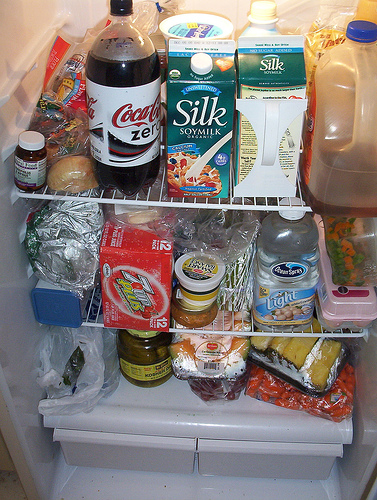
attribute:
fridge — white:
[1, 5, 375, 498]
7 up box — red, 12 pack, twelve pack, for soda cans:
[95, 211, 177, 337]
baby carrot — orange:
[336, 380, 355, 401]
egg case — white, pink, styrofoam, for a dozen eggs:
[311, 213, 375, 337]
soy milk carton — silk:
[161, 33, 238, 208]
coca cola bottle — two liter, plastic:
[82, 2, 166, 199]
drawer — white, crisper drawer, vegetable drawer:
[48, 427, 199, 483]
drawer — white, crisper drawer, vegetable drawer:
[195, 432, 348, 485]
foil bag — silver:
[20, 201, 107, 298]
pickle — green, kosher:
[114, 327, 178, 392]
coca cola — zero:
[85, 47, 163, 196]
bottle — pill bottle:
[11, 129, 50, 197]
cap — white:
[16, 131, 49, 154]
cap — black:
[109, 0, 136, 18]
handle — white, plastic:
[49, 428, 200, 454]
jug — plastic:
[298, 16, 376, 221]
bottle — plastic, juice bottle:
[247, 202, 320, 335]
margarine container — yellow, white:
[171, 248, 227, 308]